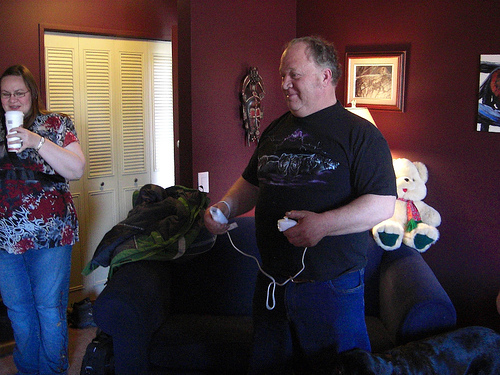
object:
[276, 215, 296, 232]
nunchuk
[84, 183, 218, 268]
coats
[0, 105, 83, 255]
shirt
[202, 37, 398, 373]
man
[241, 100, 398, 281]
shirt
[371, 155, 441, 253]
bear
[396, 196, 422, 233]
scarf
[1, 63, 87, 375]
woman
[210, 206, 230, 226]
remote control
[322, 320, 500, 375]
dog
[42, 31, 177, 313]
closet doors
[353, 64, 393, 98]
picture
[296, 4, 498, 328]
wall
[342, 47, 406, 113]
frame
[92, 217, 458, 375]
couch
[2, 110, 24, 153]
coffee cup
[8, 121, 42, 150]
hand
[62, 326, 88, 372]
floor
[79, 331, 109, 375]
bag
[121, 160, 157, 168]
slat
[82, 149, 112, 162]
slat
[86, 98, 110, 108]
slat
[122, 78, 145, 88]
slat